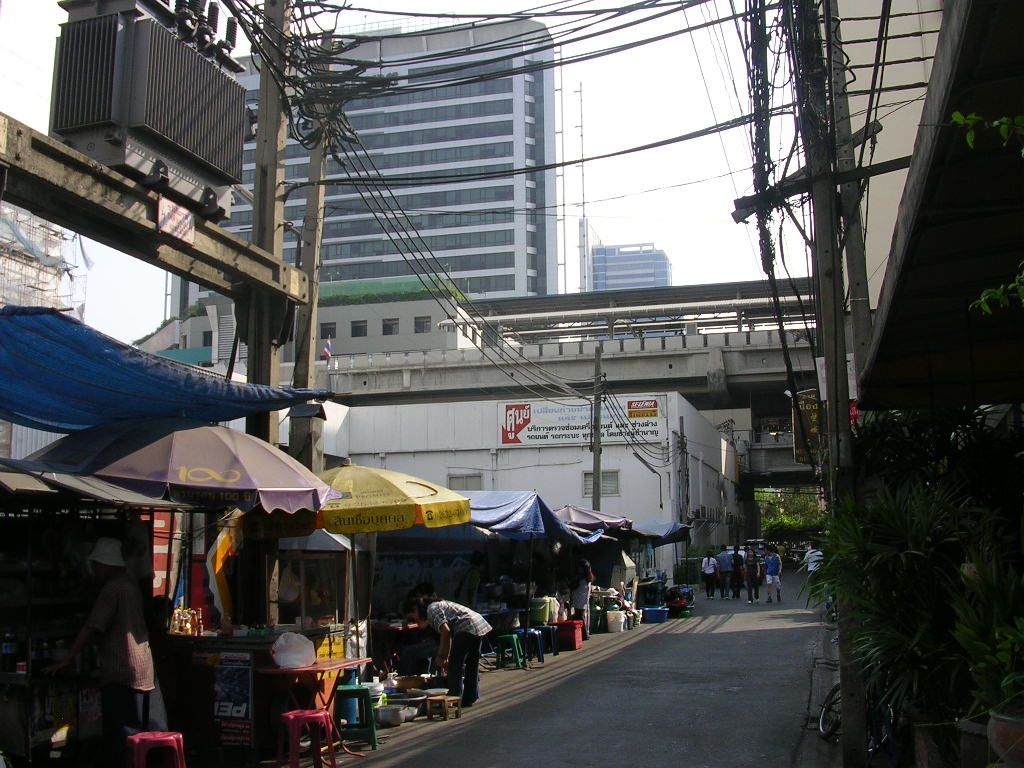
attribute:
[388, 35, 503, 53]
wall — on the side of the building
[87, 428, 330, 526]
umbrella — purple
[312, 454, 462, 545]
umbrella — yellow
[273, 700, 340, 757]
stool — red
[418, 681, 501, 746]
box — small, brown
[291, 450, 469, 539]
umbrella — yellow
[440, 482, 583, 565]
tent — blue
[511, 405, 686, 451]
sign — red, white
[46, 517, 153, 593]
hat — white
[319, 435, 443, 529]
umbrella — yellow, open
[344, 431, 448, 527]
canopy — blue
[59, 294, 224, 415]
tarp — blue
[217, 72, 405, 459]
pole — tall, wooden, utility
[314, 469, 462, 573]
umbrella — yellow, patio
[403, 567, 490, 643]
shirt — gray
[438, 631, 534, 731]
pants — black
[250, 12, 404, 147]
wire — electrical , clumped together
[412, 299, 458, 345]
window — small, square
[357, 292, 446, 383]
wall — white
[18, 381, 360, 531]
patio umbrella — lavender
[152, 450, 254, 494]
pattern — yellow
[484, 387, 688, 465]
banner — white, red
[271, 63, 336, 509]
pole — long, wooden, for electricity